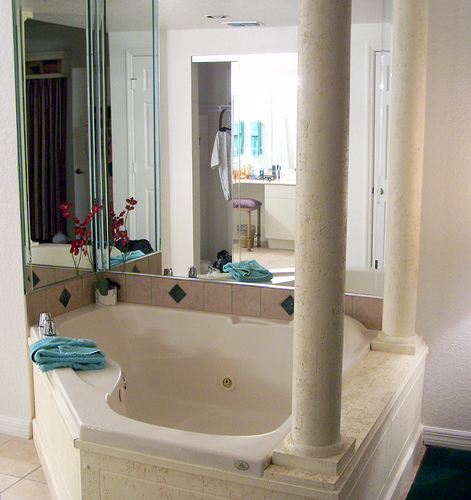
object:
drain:
[222, 375, 235, 391]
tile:
[1, 429, 46, 498]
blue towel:
[28, 335, 104, 369]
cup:
[95, 284, 118, 306]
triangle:
[168, 282, 187, 305]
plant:
[55, 201, 108, 285]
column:
[286, 1, 355, 453]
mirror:
[93, 6, 392, 293]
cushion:
[231, 196, 261, 209]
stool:
[231, 195, 261, 251]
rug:
[410, 440, 470, 498]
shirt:
[209, 128, 232, 203]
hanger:
[218, 106, 233, 132]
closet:
[189, 52, 231, 278]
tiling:
[22, 279, 384, 335]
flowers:
[60, 197, 107, 255]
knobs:
[39, 311, 56, 336]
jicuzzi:
[28, 301, 366, 493]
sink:
[211, 170, 295, 183]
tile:
[410, 446, 457, 493]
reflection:
[21, 0, 386, 298]